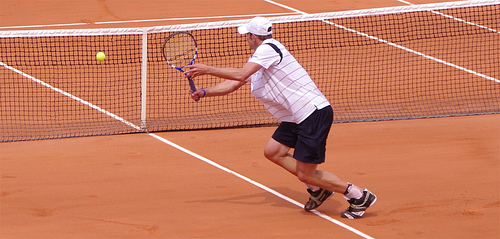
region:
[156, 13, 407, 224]
a man hitting a tennis ball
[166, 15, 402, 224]
a man swinging a tennis racket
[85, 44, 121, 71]
thetennis ball in mid air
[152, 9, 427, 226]
a man playing tennis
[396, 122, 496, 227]
the court is made of clay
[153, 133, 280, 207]
a line painted on the court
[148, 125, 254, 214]
the line is white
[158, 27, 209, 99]
the tennis racket is blue and white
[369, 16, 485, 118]
the tennis net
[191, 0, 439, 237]
a man wearing the white hat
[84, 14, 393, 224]
man playing a game of tennis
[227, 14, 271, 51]
man wearing white baseball cap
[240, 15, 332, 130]
man wearing a striped shirt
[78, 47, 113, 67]
yellow tennis ball in the air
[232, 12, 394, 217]
man wearing navy blue shorts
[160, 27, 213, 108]
black and blue tennis racket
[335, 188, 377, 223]
white and blue tennis shoes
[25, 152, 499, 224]
red clay tennis court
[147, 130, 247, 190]
boundary line on tennis court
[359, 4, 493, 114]
net in middle of tennis court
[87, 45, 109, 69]
yellow tennis ball in mid air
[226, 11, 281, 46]
white cap on tennis player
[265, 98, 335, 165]
black shorts on tennis player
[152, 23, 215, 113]
tennis racket being held by player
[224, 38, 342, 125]
white shirt with dark stripes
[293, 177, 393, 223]
black and white athletic footwear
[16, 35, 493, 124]
net in middle of tennis court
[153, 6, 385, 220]
man playing tennis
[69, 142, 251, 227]
orange tennis court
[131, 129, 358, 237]
white stripes on tennis court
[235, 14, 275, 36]
man wearing a white baseball cap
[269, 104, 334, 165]
black poly-nylon shorts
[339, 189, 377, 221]
'tennis' shoe on the man's left foot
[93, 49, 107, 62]
neon yellow tennis ball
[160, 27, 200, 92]
blue and black tennis racket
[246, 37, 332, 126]
white polo shirt with thin black stripes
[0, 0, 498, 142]
long and low to the ground tennis net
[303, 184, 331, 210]
'tennis' shoe on the man's right foot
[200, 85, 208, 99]
blue rubber bracelet on the man's right wrist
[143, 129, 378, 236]
white lines for marking boundries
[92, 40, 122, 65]
The ball is flying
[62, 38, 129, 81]
This is a tennis ball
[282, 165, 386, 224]
His shoes are white and black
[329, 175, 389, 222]
He is wearing socks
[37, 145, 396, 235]
The floor is brown and white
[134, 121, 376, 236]
A white stripe in the middle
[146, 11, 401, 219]
The man is going for the ball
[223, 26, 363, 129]
The man's shirt is stripped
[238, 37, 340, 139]
White and black is the color of his shirt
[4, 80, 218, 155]
The gate is on the ground